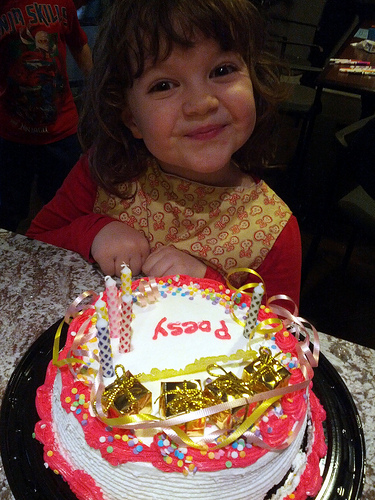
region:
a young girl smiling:
[67, 10, 315, 187]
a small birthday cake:
[61, 283, 340, 461]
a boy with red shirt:
[8, 21, 73, 119]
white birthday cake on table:
[57, 269, 372, 430]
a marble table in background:
[3, 235, 108, 310]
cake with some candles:
[72, 257, 280, 382]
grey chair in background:
[248, 21, 374, 189]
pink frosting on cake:
[49, 258, 371, 433]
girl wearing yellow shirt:
[120, 169, 304, 268]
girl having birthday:
[43, 54, 295, 456]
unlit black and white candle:
[93, 306, 116, 382]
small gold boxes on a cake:
[108, 366, 258, 434]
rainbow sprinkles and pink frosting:
[151, 433, 194, 477]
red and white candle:
[117, 288, 132, 357]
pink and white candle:
[102, 274, 120, 345]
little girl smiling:
[135, 6, 255, 170]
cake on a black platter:
[25, 302, 368, 494]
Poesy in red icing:
[141, 308, 234, 346]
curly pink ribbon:
[135, 271, 167, 306]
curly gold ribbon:
[228, 267, 252, 321]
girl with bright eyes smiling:
[35, 3, 305, 183]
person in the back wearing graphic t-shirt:
[1, 2, 92, 159]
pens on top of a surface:
[285, 7, 369, 103]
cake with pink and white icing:
[27, 256, 345, 492]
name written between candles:
[62, 256, 268, 372]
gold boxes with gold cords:
[95, 341, 292, 422]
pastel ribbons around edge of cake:
[38, 265, 318, 468]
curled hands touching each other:
[76, 206, 217, 296]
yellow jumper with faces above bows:
[33, 161, 318, 272]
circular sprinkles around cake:
[55, 266, 321, 478]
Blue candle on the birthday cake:
[94, 316, 115, 378]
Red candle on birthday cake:
[118, 298, 133, 347]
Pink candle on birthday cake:
[103, 283, 120, 338]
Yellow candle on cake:
[121, 272, 133, 296]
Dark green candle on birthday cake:
[253, 287, 264, 342]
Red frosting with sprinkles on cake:
[92, 422, 121, 455]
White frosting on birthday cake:
[142, 342, 166, 363]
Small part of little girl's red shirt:
[75, 178, 90, 203]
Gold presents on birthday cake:
[163, 380, 206, 428]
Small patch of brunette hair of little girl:
[88, 100, 119, 139]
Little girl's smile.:
[180, 119, 234, 145]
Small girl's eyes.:
[145, 64, 241, 99]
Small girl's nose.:
[180, 97, 220, 117]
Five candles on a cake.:
[94, 263, 139, 377]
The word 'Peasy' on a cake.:
[154, 312, 239, 338]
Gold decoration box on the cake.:
[161, 376, 207, 417]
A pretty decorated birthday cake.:
[29, 273, 345, 489]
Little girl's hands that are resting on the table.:
[94, 220, 208, 278]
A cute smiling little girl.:
[39, 6, 344, 278]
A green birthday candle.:
[240, 279, 265, 336]